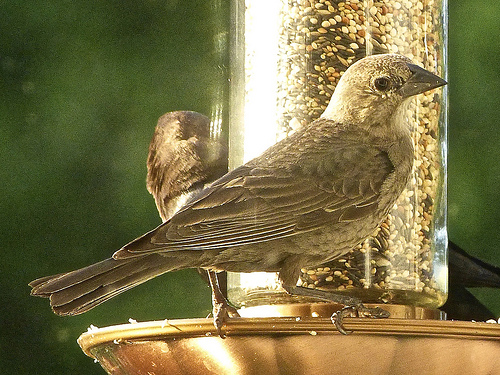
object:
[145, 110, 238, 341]
birds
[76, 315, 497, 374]
feeder base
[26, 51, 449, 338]
bird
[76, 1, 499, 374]
feeder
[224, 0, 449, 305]
glass top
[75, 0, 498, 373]
bird feeder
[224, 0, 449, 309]
glass feeder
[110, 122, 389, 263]
wing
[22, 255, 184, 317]
tail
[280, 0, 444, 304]
seeds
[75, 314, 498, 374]
dish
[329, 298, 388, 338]
bird foot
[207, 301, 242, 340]
bird foot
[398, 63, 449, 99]
beak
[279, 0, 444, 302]
bird seed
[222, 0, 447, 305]
glass tube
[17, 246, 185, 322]
tail feather